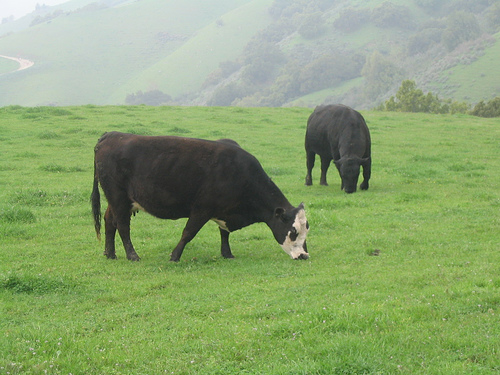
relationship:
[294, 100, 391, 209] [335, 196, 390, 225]
cow eating grass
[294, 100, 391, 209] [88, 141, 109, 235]
cow has tail